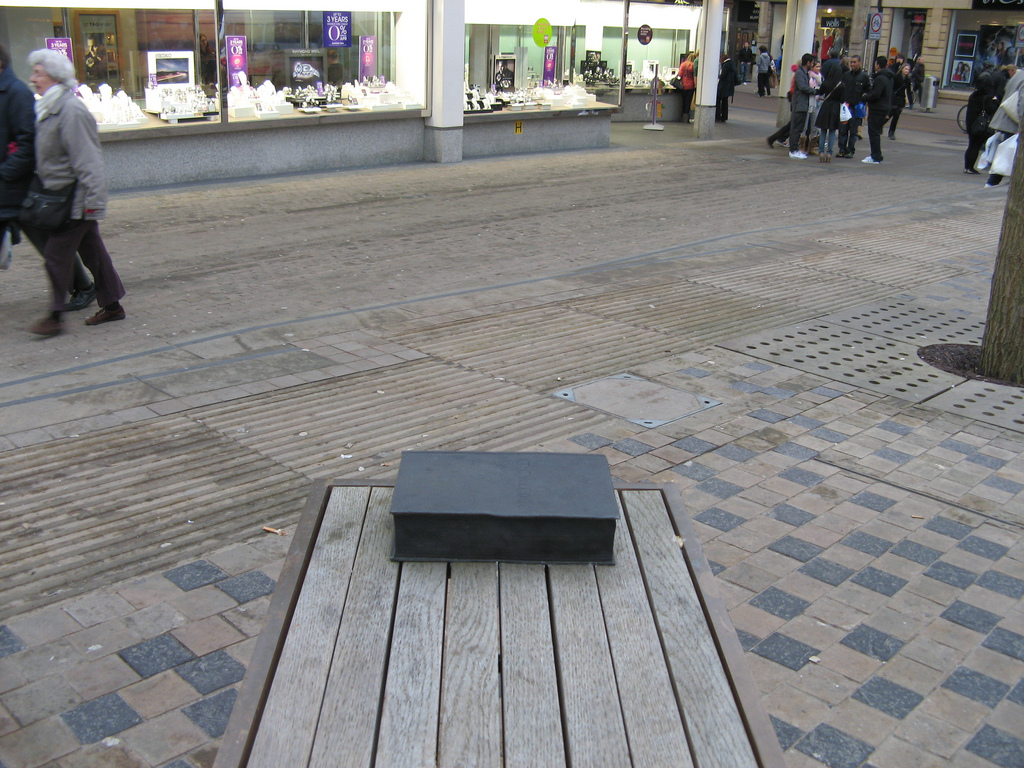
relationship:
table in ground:
[201, 472, 784, 768] [151, 323, 968, 732]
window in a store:
[62, 11, 435, 133] [0, 0, 729, 193]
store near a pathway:
[0, 0, 729, 193] [103, 211, 749, 361]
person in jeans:
[860, 56, 897, 166] [865, 105, 891, 160]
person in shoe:
[860, 56, 897, 166] [840, 141, 893, 181]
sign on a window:
[526, 14, 558, 50] [471, 10, 673, 136]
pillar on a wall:
[422, 4, 470, 169] [382, 12, 558, 144]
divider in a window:
[211, 4, 235, 135] [92, 16, 376, 144]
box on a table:
[383, 440, 628, 574] [263, 405, 756, 758]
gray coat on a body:
[27, 92, 111, 227] [26, 74, 152, 351]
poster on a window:
[318, 14, 363, 54] [125, 18, 448, 135]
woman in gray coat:
[20, 44, 126, 341] [27, 92, 107, 195]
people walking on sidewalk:
[695, 30, 987, 182] [623, 121, 833, 194]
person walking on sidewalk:
[812, 61, 880, 170] [623, 121, 833, 194]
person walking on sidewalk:
[754, 42, 809, 176] [623, 121, 833, 194]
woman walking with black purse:
[20, 44, 126, 341] [19, 171, 89, 251]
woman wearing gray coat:
[20, 44, 126, 341] [27, 92, 111, 227]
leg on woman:
[29, 186, 79, 334] [20, 44, 126, 341]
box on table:
[383, 440, 628, 574] [203, 451, 795, 745]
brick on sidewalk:
[791, 477, 824, 506] [13, 131, 1022, 752]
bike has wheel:
[950, 91, 976, 139] [950, 92, 976, 140]